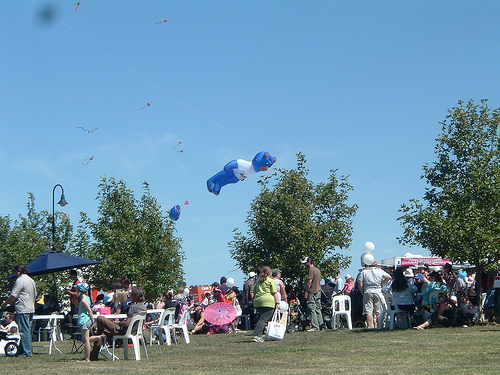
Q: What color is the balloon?
A: Blue and white.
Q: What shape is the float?
A: Bear.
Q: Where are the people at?
A: Gathering.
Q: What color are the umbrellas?
A: Blue.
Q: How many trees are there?
A: Four.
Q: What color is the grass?
A: Green.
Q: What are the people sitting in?
A: Chairs.